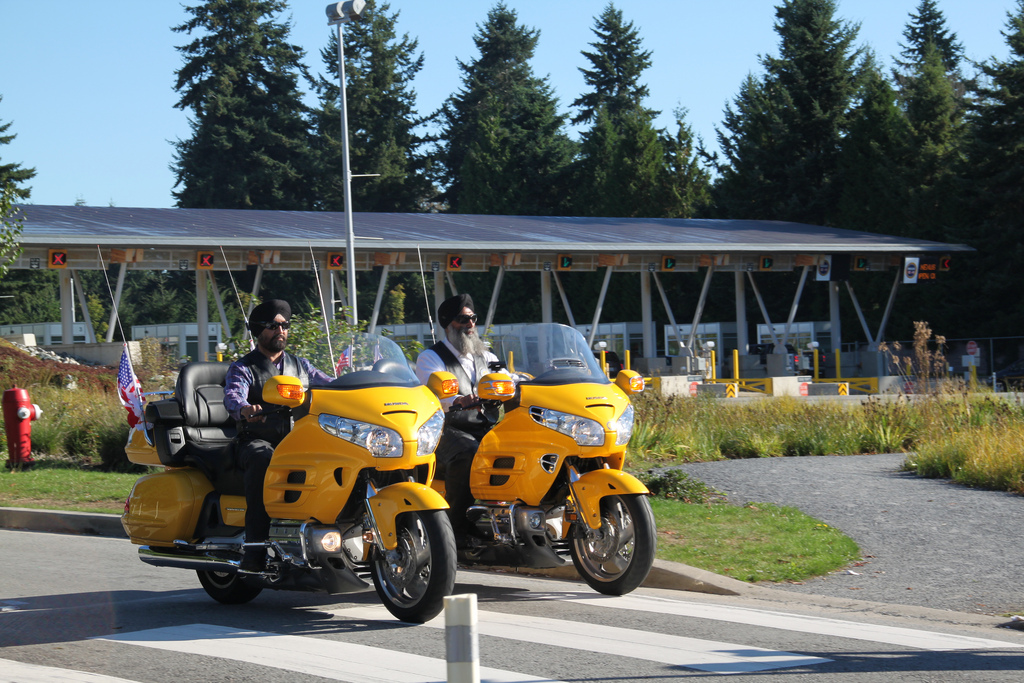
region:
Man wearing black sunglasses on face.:
[215, 300, 324, 346]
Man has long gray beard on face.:
[435, 316, 518, 359]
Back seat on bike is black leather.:
[179, 345, 247, 454]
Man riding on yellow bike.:
[100, 315, 461, 633]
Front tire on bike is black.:
[362, 495, 481, 619]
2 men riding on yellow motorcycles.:
[126, 266, 667, 596]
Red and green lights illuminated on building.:
[32, 236, 965, 284]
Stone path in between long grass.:
[711, 426, 1018, 641]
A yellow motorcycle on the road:
[118, 332, 455, 624]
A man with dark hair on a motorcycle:
[225, 300, 334, 580]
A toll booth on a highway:
[0, 202, 975, 393]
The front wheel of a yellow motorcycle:
[564, 470, 656, 592]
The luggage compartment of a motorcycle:
[118, 467, 211, 544]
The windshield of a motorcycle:
[307, 334, 415, 388]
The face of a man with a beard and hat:
[435, 288, 486, 361]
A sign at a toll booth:
[48, 247, 69, 267]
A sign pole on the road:
[326, 0, 383, 327]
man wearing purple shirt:
[221, 297, 338, 564]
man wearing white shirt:
[417, 294, 531, 481]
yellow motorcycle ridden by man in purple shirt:
[120, 292, 454, 613]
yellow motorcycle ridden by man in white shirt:
[433, 304, 662, 592]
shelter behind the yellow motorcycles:
[7, 188, 944, 407]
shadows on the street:
[13, 529, 996, 678]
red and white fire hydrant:
[7, 380, 52, 467]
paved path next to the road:
[670, 421, 1021, 638]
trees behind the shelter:
[180, 10, 1021, 309]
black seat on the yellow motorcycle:
[149, 336, 261, 476]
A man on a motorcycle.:
[218, 300, 305, 529]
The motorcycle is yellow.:
[125, 412, 461, 575]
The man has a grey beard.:
[435, 326, 480, 364]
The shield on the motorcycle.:
[480, 320, 630, 398]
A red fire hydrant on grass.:
[15, 373, 44, 454]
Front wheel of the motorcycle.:
[363, 509, 478, 627]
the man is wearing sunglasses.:
[255, 298, 301, 324]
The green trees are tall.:
[212, 12, 1022, 215]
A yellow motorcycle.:
[109, 292, 464, 625]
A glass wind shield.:
[473, 319, 609, 389]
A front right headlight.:
[316, 402, 405, 460]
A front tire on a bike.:
[357, 475, 459, 625]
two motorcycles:
[166, 272, 672, 608]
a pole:
[438, 597, 476, 668]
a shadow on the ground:
[95, 572, 213, 636]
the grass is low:
[723, 519, 775, 557]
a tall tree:
[467, 26, 544, 197]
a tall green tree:
[451, 47, 575, 188]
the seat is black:
[183, 366, 228, 437]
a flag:
[111, 342, 162, 429]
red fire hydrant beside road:
[5, 370, 73, 472]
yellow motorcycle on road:
[117, 363, 479, 624]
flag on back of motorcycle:
[97, 301, 187, 448]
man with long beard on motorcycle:
[411, 284, 533, 493]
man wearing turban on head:
[223, 282, 332, 504]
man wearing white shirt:
[411, 281, 526, 510]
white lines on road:
[84, 574, 1021, 664]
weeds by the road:
[638, 380, 1022, 495]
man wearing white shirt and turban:
[420, 287, 520, 468]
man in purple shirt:
[215, 298, 346, 469]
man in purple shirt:
[222, 290, 336, 456]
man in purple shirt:
[223, 282, 345, 451]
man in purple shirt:
[213, 291, 351, 451]